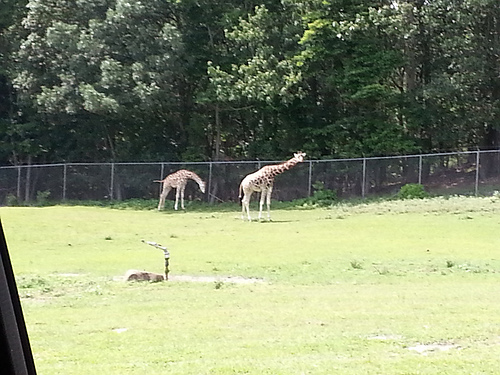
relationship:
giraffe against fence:
[238, 149, 307, 223] [1, 146, 499, 206]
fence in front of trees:
[1, 146, 499, 206] [0, 0, 499, 201]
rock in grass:
[124, 269, 165, 283] [0, 195, 499, 373]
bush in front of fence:
[392, 182, 430, 201] [1, 146, 499, 206]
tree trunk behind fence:
[115, 183, 126, 201] [1, 146, 499, 206]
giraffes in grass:
[153, 150, 306, 224] [0, 195, 499, 373]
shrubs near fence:
[1, 180, 499, 209] [1, 146, 499, 206]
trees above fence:
[0, 0, 499, 201] [1, 146, 499, 206]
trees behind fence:
[0, 0, 499, 201] [1, 146, 499, 206]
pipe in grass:
[139, 236, 170, 280] [0, 195, 499, 373]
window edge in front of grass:
[0, 216, 37, 374] [0, 195, 499, 373]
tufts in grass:
[346, 256, 456, 269] [0, 195, 499, 373]